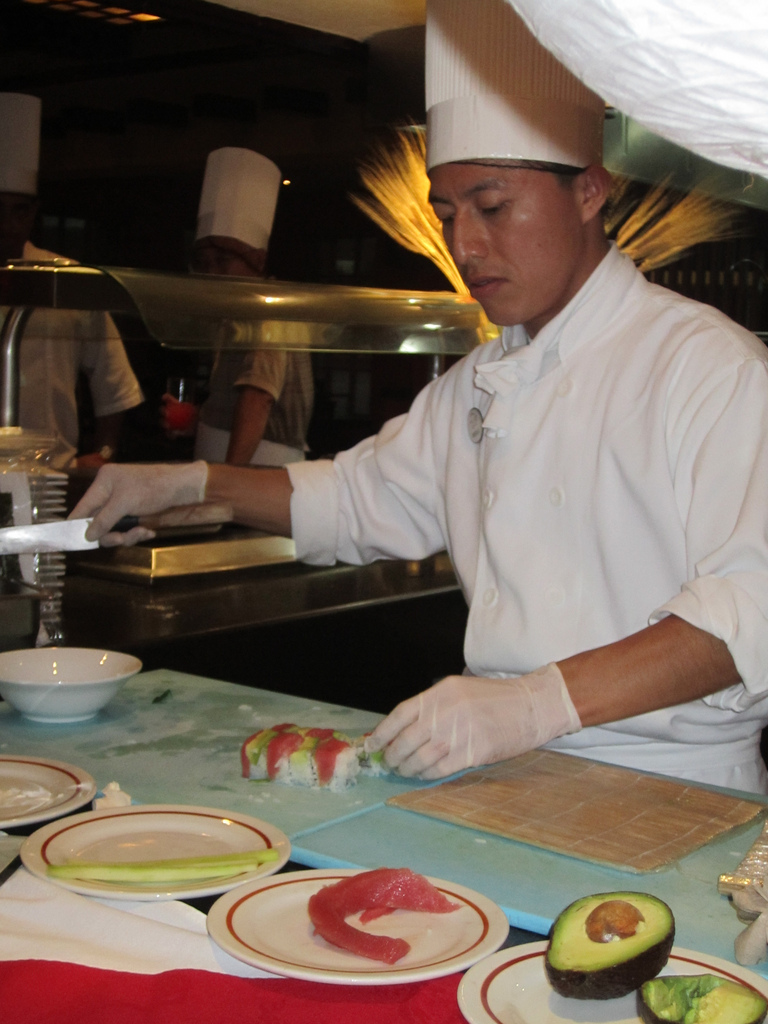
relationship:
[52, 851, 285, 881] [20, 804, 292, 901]
cucumber on plate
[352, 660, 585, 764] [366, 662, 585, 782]
glove over glove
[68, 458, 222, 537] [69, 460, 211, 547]
glove over glove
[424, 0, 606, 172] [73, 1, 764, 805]
hat on chef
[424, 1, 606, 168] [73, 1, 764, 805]
hat on chef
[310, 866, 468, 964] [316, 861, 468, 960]
food of food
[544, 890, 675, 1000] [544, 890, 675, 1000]
avocado of avocado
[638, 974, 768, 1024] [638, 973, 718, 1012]
food of food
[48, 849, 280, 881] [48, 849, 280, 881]
cucumber of cucumber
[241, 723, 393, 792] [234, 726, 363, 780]
food of food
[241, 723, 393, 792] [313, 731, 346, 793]
food of food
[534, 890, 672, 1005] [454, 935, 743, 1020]
avocado on plate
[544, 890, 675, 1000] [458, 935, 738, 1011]
avocado on plate